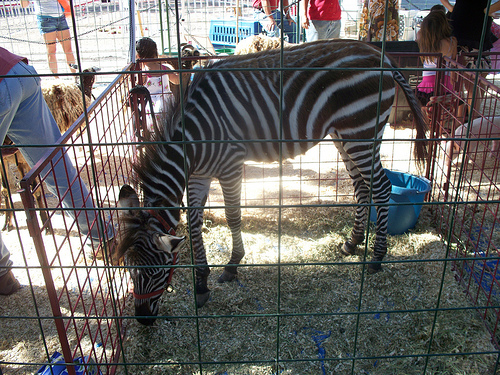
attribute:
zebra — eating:
[120, 38, 443, 325]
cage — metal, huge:
[22, 53, 499, 373]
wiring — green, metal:
[1, 1, 499, 373]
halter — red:
[130, 201, 177, 301]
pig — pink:
[442, 117, 499, 167]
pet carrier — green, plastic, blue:
[206, 20, 260, 52]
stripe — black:
[185, 101, 214, 174]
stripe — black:
[314, 73, 396, 139]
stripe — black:
[219, 66, 274, 163]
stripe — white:
[203, 71, 245, 145]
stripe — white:
[249, 68, 288, 159]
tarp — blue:
[309, 331, 334, 370]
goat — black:
[71, 62, 104, 100]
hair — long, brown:
[416, 4, 451, 62]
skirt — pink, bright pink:
[418, 76, 453, 95]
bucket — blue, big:
[361, 169, 432, 232]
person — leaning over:
[0, 47, 125, 295]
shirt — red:
[0, 47, 28, 82]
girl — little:
[134, 38, 197, 135]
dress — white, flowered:
[145, 66, 178, 134]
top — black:
[449, 1, 497, 50]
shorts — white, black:
[458, 47, 491, 73]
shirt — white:
[33, 0, 65, 18]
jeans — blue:
[0, 63, 116, 273]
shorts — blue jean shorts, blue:
[39, 15, 71, 32]